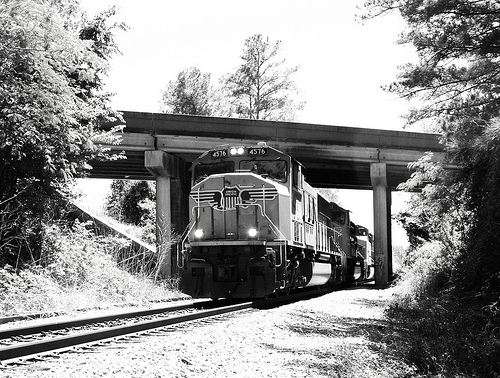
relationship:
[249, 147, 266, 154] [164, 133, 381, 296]
numbers are on train car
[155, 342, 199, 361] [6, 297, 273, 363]
gravel next to track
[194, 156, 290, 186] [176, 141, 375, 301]
windows on train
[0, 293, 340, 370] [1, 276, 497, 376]
track on ground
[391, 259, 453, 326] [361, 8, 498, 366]
leaves on tree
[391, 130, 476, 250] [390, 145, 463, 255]
leaves on tree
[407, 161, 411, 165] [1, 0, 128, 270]
leaf on tree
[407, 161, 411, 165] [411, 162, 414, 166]
leaf on leaf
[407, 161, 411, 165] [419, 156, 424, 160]
leaf on leaf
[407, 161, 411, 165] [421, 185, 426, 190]
leaf on leaf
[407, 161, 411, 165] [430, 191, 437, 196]
leaf on leaf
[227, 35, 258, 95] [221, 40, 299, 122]
leaves on tree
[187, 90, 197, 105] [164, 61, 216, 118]
leaves on tree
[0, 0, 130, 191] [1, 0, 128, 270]
leaves on tree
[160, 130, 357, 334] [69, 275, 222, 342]
train on train tracks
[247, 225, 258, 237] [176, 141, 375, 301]
headlight on train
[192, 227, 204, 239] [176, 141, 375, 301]
headlight on train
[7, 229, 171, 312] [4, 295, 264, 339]
weeds next to track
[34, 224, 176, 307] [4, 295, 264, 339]
brush next to track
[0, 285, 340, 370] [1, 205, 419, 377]
track on ground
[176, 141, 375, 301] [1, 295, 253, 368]
train on track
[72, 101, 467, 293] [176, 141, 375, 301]
bridge over train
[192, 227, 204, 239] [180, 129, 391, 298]
headlight are on train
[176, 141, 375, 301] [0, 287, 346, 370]
train on tracks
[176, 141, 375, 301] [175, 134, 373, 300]
train under a bridge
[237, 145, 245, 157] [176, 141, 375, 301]
light on top of train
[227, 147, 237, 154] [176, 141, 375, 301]
light on top of train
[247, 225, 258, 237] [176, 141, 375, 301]
headlight on top of train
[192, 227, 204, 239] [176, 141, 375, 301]
headlight on top of train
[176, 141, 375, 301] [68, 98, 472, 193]
train under a bridge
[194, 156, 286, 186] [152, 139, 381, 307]
windows on a train car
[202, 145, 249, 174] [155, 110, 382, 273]
4576 on train